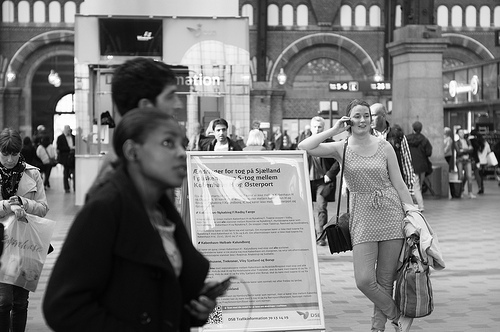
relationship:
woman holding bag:
[297, 97, 414, 330] [395, 234, 435, 321]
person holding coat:
[297, 97, 414, 330] [399, 199, 447, 276]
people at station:
[2, 57, 491, 326] [0, 0, 500, 331]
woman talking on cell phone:
[297, 97, 414, 330] [343, 116, 353, 129]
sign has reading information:
[187, 147, 327, 332] [188, 163, 320, 325]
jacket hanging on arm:
[399, 199, 447, 276] [386, 141, 416, 211]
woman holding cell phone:
[297, 97, 414, 330] [343, 116, 353, 129]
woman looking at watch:
[0, 128, 52, 332] [8, 195, 19, 206]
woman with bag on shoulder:
[297, 97, 414, 330] [320, 139, 352, 256]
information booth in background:
[71, 11, 251, 209] [1, 1, 499, 205]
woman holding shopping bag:
[0, 128, 52, 332] [1, 209, 58, 292]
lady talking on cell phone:
[297, 97, 414, 330] [343, 116, 353, 129]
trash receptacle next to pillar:
[448, 168, 466, 201] [383, 1, 449, 198]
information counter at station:
[71, 11, 251, 209] [0, 0, 500, 331]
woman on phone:
[297, 97, 414, 330] [345, 120, 355, 131]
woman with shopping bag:
[0, 128, 52, 332] [1, 209, 58, 292]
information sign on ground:
[71, 11, 251, 209] [20, 161, 499, 329]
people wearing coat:
[38, 106, 233, 331] [42, 167, 211, 331]